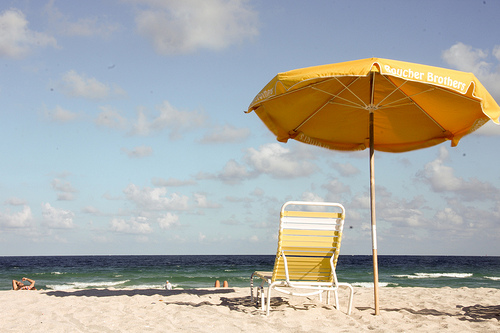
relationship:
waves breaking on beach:
[395, 265, 477, 285] [384, 283, 498, 324]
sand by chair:
[187, 308, 197, 327] [244, 200, 355, 313]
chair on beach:
[244, 200, 355, 313] [81, 314, 333, 329]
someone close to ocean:
[165, 270, 175, 293] [76, 259, 247, 272]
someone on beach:
[165, 270, 175, 293] [133, 294, 164, 302]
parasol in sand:
[244, 54, 499, 153] [339, 314, 431, 329]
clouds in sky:
[38, 171, 222, 250] [10, 10, 314, 187]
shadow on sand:
[47, 286, 237, 297] [46, 298, 225, 328]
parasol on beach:
[244, 54, 499, 153] [160, 305, 415, 330]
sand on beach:
[127, 310, 170, 326] [8, 295, 238, 327]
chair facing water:
[244, 200, 355, 313] [43, 256, 222, 277]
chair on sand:
[244, 200, 355, 313] [29, 298, 150, 330]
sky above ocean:
[24, 95, 244, 190] [22, 251, 262, 291]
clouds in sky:
[92, 171, 222, 241] [13, 114, 258, 223]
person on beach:
[8, 272, 40, 288] [6, 294, 149, 330]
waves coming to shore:
[30, 254, 235, 292] [3, 283, 242, 330]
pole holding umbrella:
[351, 86, 406, 325] [238, 49, 490, 175]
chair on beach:
[244, 200, 355, 313] [0, 273, 486, 331]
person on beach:
[8, 275, 39, 290] [5, 283, 498, 323]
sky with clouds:
[3, 9, 492, 255] [52, 57, 240, 200]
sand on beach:
[19, 278, 279, 328] [0, 273, 486, 331]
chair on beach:
[231, 205, 363, 315] [0, 273, 486, 331]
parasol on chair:
[244, 54, 499, 153] [231, 205, 363, 315]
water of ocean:
[6, 255, 498, 265] [0, 258, 499, 296]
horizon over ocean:
[7, 239, 490, 260] [3, 259, 497, 291]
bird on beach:
[159, 275, 181, 299] [3, 282, 497, 331]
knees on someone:
[211, 277, 228, 291] [205, 268, 235, 300]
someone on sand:
[205, 268, 235, 300] [6, 290, 498, 330]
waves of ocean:
[395, 265, 477, 285] [0, 256, 498, 293]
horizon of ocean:
[7, 239, 490, 260] [5, 254, 495, 287]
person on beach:
[8, 275, 39, 290] [0, 273, 486, 331]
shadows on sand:
[45, 281, 237, 306] [6, 290, 498, 330]